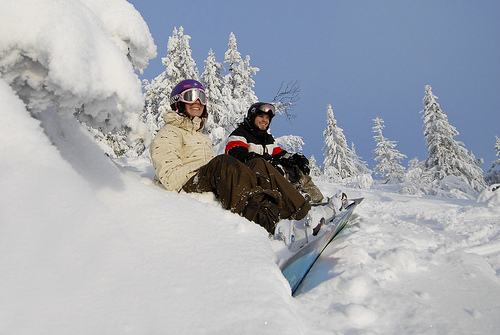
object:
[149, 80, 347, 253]
couple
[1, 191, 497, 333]
snow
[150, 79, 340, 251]
woman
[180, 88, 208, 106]
goggles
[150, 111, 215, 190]
coat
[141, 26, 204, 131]
tree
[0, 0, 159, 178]
snow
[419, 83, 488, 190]
tree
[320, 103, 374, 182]
tree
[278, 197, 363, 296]
snowboard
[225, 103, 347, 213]
man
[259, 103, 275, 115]
goggles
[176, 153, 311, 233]
pants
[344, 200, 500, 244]
tracks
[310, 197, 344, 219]
snowboots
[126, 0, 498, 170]
sky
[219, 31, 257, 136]
trees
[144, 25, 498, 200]
snow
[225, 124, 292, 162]
coat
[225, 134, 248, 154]
stripes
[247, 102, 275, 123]
helmet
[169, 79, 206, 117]
helmet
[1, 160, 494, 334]
ground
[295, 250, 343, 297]
shadow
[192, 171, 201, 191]
snow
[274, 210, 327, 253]
snowboots